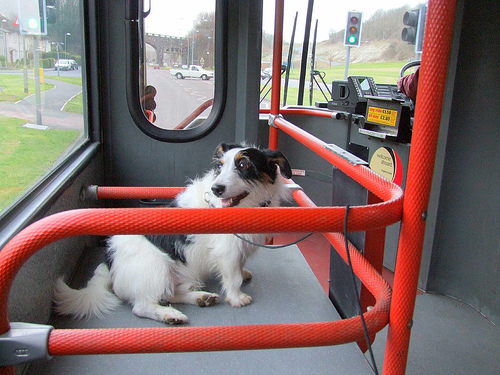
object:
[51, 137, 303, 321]
dog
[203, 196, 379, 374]
leash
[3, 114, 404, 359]
handrail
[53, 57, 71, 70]
car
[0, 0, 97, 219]
window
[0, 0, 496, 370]
bus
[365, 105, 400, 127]
sticker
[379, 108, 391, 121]
fares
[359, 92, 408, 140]
farebox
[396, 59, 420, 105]
driver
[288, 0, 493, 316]
right of bus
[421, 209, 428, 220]
bolt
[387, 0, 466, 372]
post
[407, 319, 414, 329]
bolt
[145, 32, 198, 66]
bridge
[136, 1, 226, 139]
window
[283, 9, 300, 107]
wiper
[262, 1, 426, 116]
windshield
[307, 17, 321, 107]
wiper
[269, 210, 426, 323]
floor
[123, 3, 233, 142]
rubber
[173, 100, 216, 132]
railing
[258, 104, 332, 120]
railing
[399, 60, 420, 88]
steering wheel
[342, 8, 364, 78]
traffic light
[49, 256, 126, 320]
tail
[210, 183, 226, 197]
nose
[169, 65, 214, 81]
truck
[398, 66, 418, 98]
arm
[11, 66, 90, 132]
sidewalk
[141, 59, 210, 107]
road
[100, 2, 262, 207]
door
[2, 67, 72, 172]
grass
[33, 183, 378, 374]
seat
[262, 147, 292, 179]
ear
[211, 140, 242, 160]
ear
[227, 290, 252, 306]
paw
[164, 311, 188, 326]
paw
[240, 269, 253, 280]
paw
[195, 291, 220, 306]
paw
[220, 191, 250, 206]
mouth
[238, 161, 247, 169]
eye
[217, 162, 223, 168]
eye